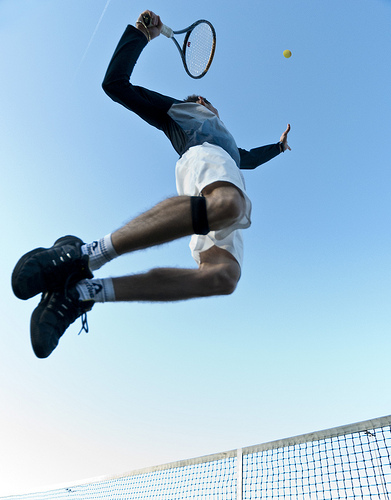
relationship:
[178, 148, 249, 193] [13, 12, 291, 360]
shorts on player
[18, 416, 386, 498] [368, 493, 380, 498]
net on court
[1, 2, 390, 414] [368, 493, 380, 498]
sky above court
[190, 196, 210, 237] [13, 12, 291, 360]
band on player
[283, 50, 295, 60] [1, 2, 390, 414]
ball in sky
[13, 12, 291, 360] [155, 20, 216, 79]
player swinging racket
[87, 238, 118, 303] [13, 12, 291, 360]
socks on player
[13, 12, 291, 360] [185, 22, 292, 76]
jumping to hit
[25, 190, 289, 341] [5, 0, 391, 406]
jumping in air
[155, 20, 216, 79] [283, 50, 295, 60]
racket hitting ball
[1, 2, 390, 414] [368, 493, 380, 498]
sky over court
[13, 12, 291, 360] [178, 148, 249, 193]
player has shorts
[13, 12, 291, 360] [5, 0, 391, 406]
player in air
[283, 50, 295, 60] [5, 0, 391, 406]
ball in air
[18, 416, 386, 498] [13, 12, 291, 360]
net under player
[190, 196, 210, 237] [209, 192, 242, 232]
band under knee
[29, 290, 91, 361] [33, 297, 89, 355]
sneaker on left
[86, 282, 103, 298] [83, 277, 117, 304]
design on sock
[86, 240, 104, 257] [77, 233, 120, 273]
design on socks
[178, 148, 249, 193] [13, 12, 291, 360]
shorts worn player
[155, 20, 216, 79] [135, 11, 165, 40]
racket in hand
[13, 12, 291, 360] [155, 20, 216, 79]
player holds racket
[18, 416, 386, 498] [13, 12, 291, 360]
net front player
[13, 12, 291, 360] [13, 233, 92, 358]
player wears sneakers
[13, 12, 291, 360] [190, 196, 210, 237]
player has band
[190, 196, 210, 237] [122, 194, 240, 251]
band around leg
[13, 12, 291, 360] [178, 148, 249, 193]
player wears shorts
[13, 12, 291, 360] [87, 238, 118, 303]
player has socks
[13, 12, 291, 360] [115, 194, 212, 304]
player has legs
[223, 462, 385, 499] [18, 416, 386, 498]
string on net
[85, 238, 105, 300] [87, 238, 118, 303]
logo on socks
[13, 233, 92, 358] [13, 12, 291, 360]
sneakers on player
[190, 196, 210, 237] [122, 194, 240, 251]
band on leg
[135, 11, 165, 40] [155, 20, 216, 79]
hand on racket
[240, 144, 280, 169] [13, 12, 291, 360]
sleaves on player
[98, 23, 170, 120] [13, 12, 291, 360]
sleaves on player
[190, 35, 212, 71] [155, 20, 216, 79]
string on racket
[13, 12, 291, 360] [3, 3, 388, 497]
player in air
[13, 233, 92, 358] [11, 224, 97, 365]
sneakers on feet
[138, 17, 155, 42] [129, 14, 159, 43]
bracelet on wrist